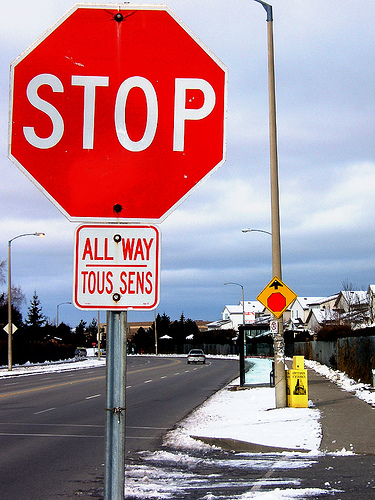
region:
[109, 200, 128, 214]
screw on bottom of stop sign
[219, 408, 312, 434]
snow on the grass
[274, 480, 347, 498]
snow on the sidewalk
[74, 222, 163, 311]
white and red all way signe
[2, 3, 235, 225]
red stop sign on pole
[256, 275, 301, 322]
yellow traffic sign on pole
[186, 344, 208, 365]
silver car on the road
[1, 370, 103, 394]
yelllow lines in the road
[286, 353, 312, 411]
yellow newspaper vending machine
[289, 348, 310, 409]
the newspaper stand is yellow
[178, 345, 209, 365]
the car is silver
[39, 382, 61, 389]
the line is yellow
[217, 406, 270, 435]
snow is between the sidewalk and the road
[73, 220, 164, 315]
the sign is square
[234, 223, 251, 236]
the light is off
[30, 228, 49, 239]
the street light is on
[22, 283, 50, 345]
the tree is pointed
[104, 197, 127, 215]
the screw is rusted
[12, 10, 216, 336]
all way stop sign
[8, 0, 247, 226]
typical red and white stop sign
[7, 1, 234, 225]
standard red and white stop sign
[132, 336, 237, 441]
one car on the road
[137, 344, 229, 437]
one car driving on road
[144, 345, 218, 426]
gray car on road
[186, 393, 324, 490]
snow on sidewalk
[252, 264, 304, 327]
sign indicating stop sign ahead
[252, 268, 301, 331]
yellow caution sign with red and black print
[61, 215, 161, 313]
traffic sign in two languages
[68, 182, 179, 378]
sign on a pole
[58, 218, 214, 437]
sign on a metal pole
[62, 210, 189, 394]
pole with a sign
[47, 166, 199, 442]
stop sign on a ople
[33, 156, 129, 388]
stop sign on a metal pole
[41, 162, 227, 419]
metal pole with stop sign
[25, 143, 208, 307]
red and white sign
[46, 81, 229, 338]
red and white stop sign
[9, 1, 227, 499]
red and white stop sign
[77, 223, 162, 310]
square red and white sign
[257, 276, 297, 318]
yellow red and black diamond sign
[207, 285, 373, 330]
white snow on house roofs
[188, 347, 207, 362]
silver car driving forward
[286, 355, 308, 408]
yellow and black newspaper dispenser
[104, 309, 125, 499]
silver sign pole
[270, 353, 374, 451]
clear sidewalk with no snow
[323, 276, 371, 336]
tree with no leaves in front of house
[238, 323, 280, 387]
black and clear bus stop shelter